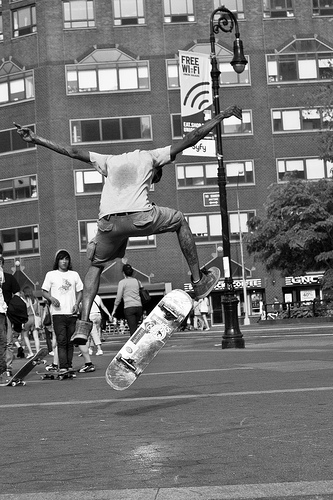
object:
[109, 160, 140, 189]
sweat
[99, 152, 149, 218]
back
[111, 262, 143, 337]
woman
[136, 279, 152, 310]
purse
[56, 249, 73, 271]
head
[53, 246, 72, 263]
cap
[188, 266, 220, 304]
shoes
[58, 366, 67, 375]
foot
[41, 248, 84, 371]
guy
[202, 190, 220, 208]
sign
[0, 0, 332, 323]
building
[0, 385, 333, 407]
line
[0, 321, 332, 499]
ground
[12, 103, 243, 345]
man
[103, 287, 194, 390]
skateboard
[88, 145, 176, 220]
shirt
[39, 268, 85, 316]
shirt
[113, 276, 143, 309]
shirt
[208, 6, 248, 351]
lamp post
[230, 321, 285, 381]
air